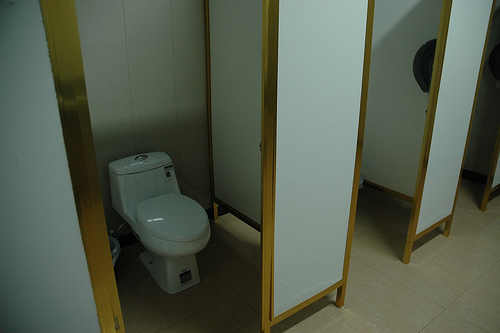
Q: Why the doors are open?
A: No one in the cubicle.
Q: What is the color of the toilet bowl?
A: White.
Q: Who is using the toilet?
A: No one.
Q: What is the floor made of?
A: Marble.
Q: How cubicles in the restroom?
A: Three.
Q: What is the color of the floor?
A: Beige.